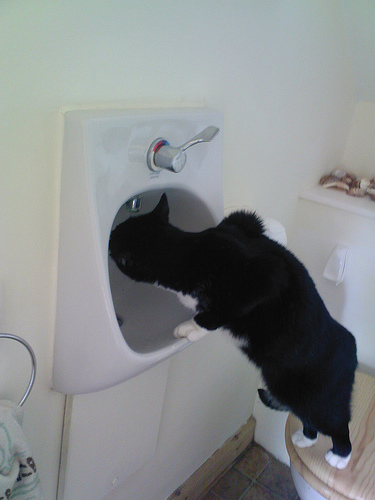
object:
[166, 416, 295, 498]
baseboard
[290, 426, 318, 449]
foot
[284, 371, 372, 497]
toilet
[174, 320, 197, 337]
foot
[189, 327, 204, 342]
foot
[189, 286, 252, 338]
leg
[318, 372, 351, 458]
leg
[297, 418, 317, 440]
leg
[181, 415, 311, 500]
tile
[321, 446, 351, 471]
feet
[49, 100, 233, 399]
sink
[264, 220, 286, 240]
edge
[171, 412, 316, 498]
floor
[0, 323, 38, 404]
hoop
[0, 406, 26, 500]
towel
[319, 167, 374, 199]
items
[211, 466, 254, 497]
tile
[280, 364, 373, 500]
toilet seat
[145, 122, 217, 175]
handle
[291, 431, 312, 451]
cat paw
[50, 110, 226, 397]
appliance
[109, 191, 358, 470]
black cat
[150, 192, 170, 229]
ear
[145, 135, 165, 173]
harware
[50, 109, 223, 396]
porceline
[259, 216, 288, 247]
toilet paper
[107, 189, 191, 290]
head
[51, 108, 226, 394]
urinal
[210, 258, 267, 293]
fur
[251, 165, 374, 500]
toilet